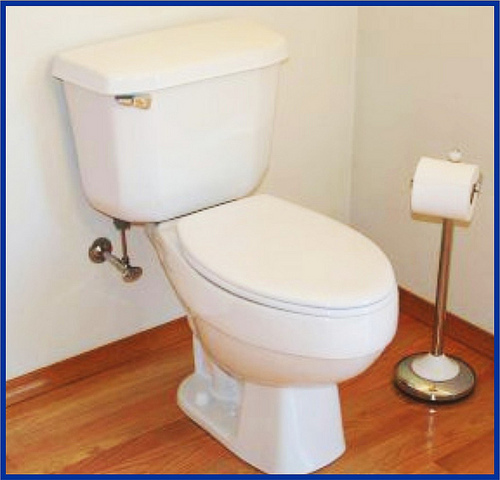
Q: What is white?
A: The toilet.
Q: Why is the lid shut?
A: The toilet is not in use.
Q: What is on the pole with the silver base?
A: A toilet paper role and paper.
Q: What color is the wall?
A: White.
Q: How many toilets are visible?
A: One.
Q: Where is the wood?
A: On the floor.